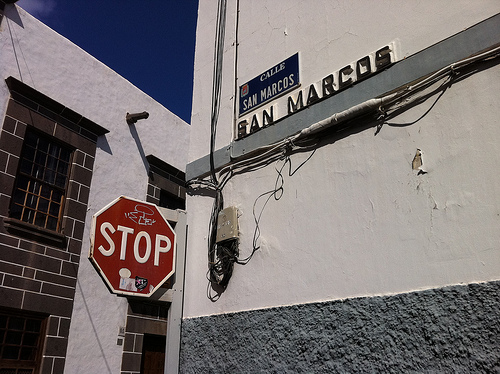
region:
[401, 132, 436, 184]
a tare in the side of a building.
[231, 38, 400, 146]
writing on the side of a building.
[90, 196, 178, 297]
a red stop sign on a building.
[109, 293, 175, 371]
a section of bricks on a building.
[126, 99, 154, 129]
a light on the side of a building.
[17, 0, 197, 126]
a clear blue sky.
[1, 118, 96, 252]
a second story window.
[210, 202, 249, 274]
an electric box on a building.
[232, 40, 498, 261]
wires on the side of a building.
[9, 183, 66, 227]
a wood railing.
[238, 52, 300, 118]
blue sign with white writing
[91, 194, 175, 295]
red sign with white writing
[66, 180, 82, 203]
brick is next to bick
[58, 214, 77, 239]
brick is next to bick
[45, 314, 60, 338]
brick is next to bick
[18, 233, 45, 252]
brick is next to bick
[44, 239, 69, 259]
brick is next to bick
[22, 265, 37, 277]
brick is next to bick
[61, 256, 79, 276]
brick is next to bick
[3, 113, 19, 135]
brick is next to bick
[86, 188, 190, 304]
a red stop sign.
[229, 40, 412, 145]
A san marcos sign.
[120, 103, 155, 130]
a light in an alley.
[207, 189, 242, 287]
an electronic device on a building.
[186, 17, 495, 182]
a blue border on a building.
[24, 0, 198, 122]
a section of a clear sky.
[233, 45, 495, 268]
wires on a building.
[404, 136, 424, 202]
damage on the side of a building.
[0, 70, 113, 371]
a section of brick on a building.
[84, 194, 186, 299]
A red stop sign.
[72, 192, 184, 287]
Red sign attached to building.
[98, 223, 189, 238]
White writing on sign.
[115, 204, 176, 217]
Graffiti on red sign.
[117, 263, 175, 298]
Stickers stuck to bottom of sign.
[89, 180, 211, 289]
Red sign attached to gray pole.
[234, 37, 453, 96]
Black letters on side of building.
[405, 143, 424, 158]
Paint missing on side of building.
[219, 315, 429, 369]
Gray stucco on side of building.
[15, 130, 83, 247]
Metal bars over window on building.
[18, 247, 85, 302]
Brown bricks on side of building.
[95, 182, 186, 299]
that is a road sign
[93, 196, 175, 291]
the road sign says stop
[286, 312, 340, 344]
that is a wall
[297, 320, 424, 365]
that wall is rough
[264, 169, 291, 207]
that is a wire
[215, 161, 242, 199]
that is a wire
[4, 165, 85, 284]
that is a brick wall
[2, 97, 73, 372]
the brick wall is brown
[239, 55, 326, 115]
that is a sign board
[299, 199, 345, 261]
that is a wall